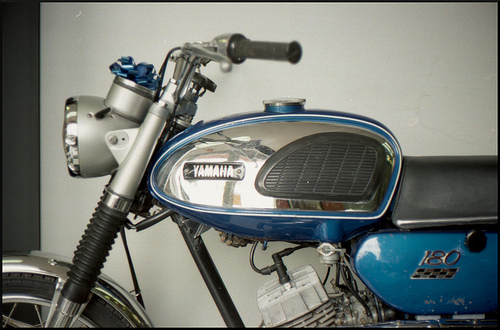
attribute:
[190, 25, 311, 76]
handles — black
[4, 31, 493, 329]
bike — silver, chrome, blue, strong, black, shiny, new, nice, gray, clean, a yamaha, bule, vintage, old, painted blue, detailed, plastic, metal, leather, fancy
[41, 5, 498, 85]
wall — white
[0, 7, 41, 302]
wall — black